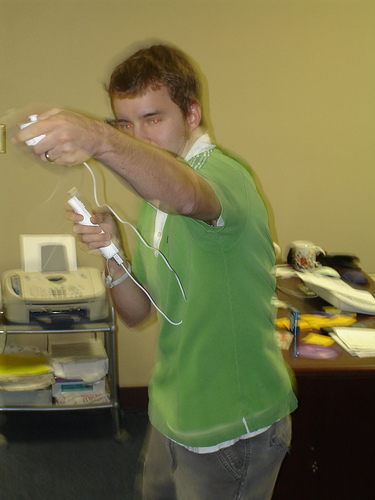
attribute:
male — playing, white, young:
[12, 43, 299, 499]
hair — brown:
[101, 44, 206, 136]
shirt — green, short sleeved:
[131, 132, 299, 447]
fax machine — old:
[4, 244, 108, 331]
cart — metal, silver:
[0, 289, 133, 446]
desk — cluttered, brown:
[272, 260, 374, 499]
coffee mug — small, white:
[293, 243, 325, 272]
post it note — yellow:
[301, 332, 333, 348]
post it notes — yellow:
[274, 306, 357, 346]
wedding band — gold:
[43, 151, 53, 163]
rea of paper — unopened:
[51, 379, 106, 399]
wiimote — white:
[69, 196, 120, 260]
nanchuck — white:
[19, 114, 47, 148]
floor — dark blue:
[0, 409, 147, 499]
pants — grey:
[140, 413, 293, 498]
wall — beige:
[1, 1, 374, 389]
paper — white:
[20, 235, 79, 273]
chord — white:
[81, 161, 188, 327]